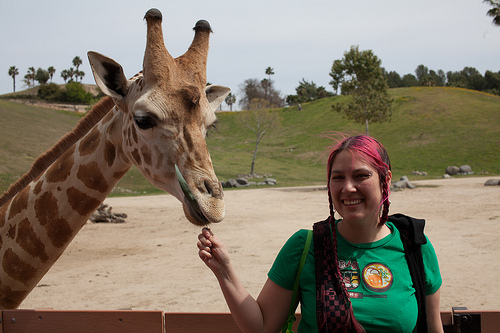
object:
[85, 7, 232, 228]
head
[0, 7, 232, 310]
giraffe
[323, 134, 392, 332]
hair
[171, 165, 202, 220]
first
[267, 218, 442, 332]
shirt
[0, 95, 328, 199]
hill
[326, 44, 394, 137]
tree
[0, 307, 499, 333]
fence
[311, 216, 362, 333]
bag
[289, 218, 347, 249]
shoulder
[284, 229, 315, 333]
strap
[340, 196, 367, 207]
smile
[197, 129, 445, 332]
woman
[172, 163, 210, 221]
leaf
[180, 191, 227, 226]
mouth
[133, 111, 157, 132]
eye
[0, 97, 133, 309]
neck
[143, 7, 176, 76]
horn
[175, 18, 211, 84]
horn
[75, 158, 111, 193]
spot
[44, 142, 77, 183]
spot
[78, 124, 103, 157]
spot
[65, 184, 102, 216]
spot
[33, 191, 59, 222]
spot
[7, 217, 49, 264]
spot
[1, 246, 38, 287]
spot